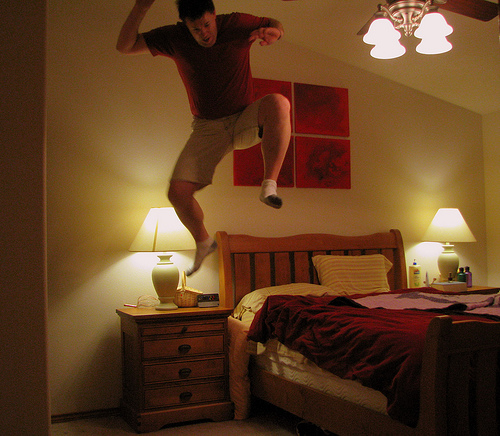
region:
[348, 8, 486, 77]
Lights on a celing fan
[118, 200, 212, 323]
A lamp on a nightstand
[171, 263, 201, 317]
A basket next to a lamp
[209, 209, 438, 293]
A wooden bed frame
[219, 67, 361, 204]
A four part picture on the wall above the bed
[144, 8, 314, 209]
A man jumping in the air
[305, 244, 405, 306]
A pillow leaning on a headboard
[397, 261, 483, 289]
Bottles on a nightstand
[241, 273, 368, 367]
A rumpled blanket on a bed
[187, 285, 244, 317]
An alarm clock on a nightstand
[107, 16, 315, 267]
The man is jumping in the air.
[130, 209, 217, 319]
The lamp is turned on.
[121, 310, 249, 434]
The nightstand has four drawers.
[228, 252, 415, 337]
The pillows are on the bed.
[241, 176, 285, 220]
The man has on white socks.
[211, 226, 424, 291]
The headboard is made of wood.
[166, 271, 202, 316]
A basket sits on the nightstand.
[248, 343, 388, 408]
The mattress is white.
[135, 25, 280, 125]
The man is wearing a red shirt.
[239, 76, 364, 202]
The picture on the wall is red.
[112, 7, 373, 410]
man jumping in air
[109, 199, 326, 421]
lamp turned on next to bed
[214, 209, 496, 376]
wood frame bed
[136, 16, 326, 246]
man wearing shorts and shirt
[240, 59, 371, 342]
paintings on wall over bed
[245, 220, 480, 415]
bed has red blanket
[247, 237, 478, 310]
bed has two pillows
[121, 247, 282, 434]
bedside table has drawers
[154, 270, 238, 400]
basket sitting on bedside table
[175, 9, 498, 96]
four light chandelier near man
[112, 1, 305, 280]
the man is jumping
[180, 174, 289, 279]
the man is wearing socks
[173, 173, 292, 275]
the socks are white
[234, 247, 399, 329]
the bed has two pillows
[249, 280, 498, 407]
the bed has a red spread on it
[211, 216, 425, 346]
the bed has a wooden head board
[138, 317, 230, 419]
the side table has 4 drawers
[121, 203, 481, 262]
the lamps have white shades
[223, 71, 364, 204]
4 pictures are hanging on the wall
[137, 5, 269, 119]
the man is wearing a red shirt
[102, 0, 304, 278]
Man jumping in the air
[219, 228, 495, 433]
Unmade bed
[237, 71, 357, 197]
Red painting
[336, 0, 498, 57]
On ceiling light and fan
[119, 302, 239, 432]
Night stand next to a bed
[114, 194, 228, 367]
Lamp on top of a night stand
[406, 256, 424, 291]
Bottle of lotion next to a bed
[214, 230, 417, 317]
Wooden headboard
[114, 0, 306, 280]
Man wearing red shirt and khaki shorts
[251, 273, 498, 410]
Red blanket on top of a bed